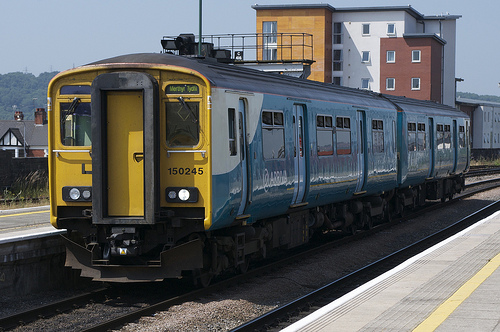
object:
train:
[47, 51, 471, 287]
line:
[408, 239, 500, 332]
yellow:
[465, 281, 478, 289]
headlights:
[168, 189, 192, 201]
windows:
[316, 116, 354, 156]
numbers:
[167, 164, 204, 178]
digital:
[162, 85, 201, 93]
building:
[159, 5, 464, 105]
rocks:
[199, 308, 230, 326]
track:
[47, 51, 471, 284]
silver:
[165, 149, 208, 155]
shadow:
[195, 230, 355, 302]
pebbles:
[157, 303, 230, 327]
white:
[69, 188, 80, 200]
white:
[363, 286, 370, 291]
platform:
[278, 210, 499, 331]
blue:
[343, 266, 359, 282]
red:
[397, 43, 407, 57]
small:
[381, 37, 443, 103]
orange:
[305, 13, 325, 30]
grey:
[32, 138, 44, 146]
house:
[0, 108, 51, 160]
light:
[69, 189, 93, 202]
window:
[262, 109, 287, 161]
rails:
[0, 160, 500, 331]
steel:
[231, 302, 306, 331]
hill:
[0, 70, 61, 120]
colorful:
[314, 13, 416, 58]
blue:
[272, 96, 285, 109]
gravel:
[199, 315, 229, 329]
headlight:
[177, 188, 193, 202]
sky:
[0, 0, 161, 55]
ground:
[272, 210, 499, 330]